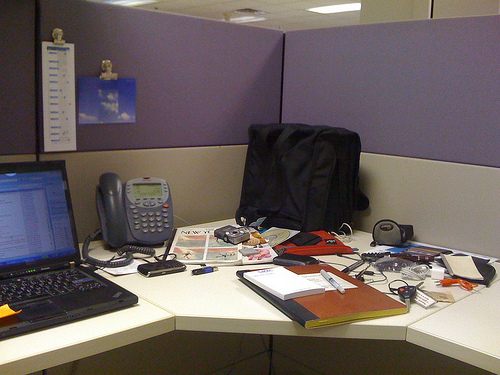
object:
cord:
[79, 227, 156, 269]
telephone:
[135, 257, 189, 279]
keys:
[396, 283, 418, 314]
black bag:
[232, 122, 370, 237]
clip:
[98, 58, 120, 82]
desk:
[0, 216, 500, 375]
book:
[233, 261, 411, 332]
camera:
[211, 223, 251, 246]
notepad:
[241, 265, 327, 302]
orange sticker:
[0, 303, 24, 320]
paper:
[77, 74, 138, 125]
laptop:
[0, 157, 142, 340]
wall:
[0, 1, 499, 166]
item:
[368, 217, 416, 249]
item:
[438, 251, 485, 282]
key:
[141, 222, 149, 228]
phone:
[90, 169, 177, 251]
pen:
[319, 268, 347, 295]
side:
[0, 314, 176, 375]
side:
[174, 314, 406, 341]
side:
[403, 325, 499, 375]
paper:
[40, 41, 79, 154]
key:
[141, 217, 148, 222]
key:
[134, 220, 140, 224]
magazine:
[160, 227, 280, 267]